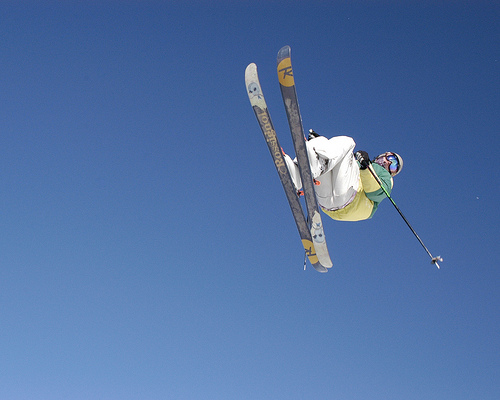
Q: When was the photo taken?
A: Daytime.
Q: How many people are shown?
A: One.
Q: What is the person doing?
A: Skiing.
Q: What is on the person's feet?
A: Skis.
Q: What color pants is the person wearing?
A: White.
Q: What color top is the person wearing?
A: Green and yellow.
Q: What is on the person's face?
A: Goggles.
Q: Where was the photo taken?
A: Ski slopes.